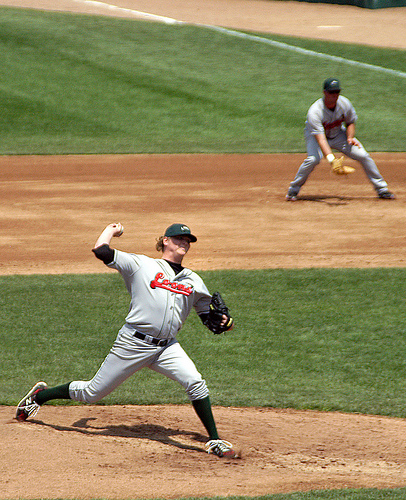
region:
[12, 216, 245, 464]
A pitcher throwing the ball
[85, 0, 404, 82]
White line on the field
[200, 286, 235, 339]
A black leather glove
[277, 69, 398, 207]
Baseball player in position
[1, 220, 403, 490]
Pitcher on the pitcher's mound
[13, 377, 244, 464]
A pair of sneakers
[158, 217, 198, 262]
Hat on man's head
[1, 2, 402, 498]
Green grass on the field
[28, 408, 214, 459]
Shadow on the dirt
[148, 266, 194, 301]
Red writing on a uniform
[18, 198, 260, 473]
baseball player on the mound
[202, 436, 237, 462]
foot of the player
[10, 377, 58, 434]
foot of the player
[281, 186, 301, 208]
foot of the player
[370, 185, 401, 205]
foot of the player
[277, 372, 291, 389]
patch of green grass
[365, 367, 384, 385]
patch of green grass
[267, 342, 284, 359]
patch of green grass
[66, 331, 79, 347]
patch of green grass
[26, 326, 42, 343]
patch of green grass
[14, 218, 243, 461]
A man getting ready to throw a ball.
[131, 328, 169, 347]
A black belt.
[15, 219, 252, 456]
A baseball player.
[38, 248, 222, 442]
A baseball uniform.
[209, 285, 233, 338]
A black baseball glove.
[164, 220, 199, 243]
A dark colored baseball hat.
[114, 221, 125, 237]
A baseball.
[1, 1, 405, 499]
A baseball field.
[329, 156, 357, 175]
A brown baseball glove.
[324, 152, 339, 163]
A white wristband.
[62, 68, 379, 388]
a baseball game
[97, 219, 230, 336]
a man throwing a ball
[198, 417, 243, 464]
clets digging into earth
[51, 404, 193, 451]
shadow of baseball player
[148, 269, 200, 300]
uniform with red lettering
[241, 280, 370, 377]
cut green turf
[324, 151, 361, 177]
a baseball players mitt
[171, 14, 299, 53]
white lines on baseball field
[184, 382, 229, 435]
a baseball player with black socks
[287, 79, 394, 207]
a baseball player stooping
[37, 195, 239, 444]
baseball player on field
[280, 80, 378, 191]
baseball player on field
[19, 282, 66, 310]
short green and brown grass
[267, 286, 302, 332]
short green and brown grass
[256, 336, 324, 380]
short green and brown grass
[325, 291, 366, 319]
short green and brown grass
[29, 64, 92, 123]
short green and brown grass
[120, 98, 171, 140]
short green and brown grass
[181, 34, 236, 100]
short green and brown grass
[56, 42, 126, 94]
short green and brown grass